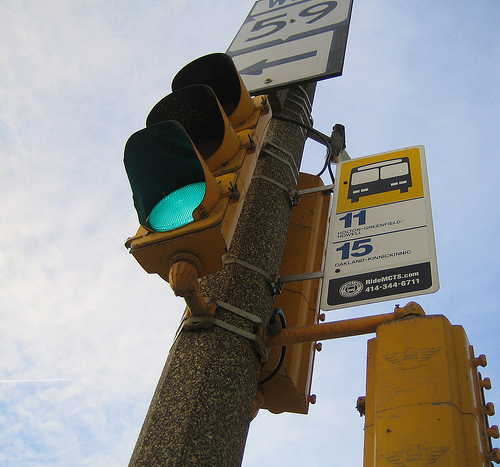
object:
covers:
[124, 119, 223, 233]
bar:
[297, 184, 334, 196]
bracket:
[224, 259, 273, 281]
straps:
[252, 175, 289, 193]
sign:
[320, 145, 439, 311]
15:
[336, 238, 373, 260]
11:
[339, 210, 366, 228]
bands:
[169, 316, 269, 355]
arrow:
[238, 50, 317, 75]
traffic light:
[123, 52, 272, 275]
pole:
[130, 82, 331, 467]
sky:
[3, 3, 129, 120]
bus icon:
[347, 156, 412, 203]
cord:
[271, 114, 333, 177]